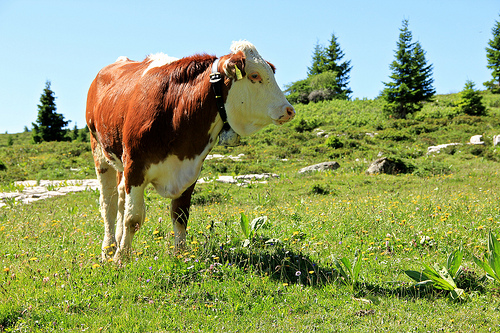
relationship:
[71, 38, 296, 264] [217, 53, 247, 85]
cow has ear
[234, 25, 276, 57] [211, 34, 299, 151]
lump on head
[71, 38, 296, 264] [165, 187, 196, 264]
cow has leg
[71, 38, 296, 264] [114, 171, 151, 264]
cow has leg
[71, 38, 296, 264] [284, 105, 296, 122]
cow has nose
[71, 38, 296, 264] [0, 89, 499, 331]
cow in field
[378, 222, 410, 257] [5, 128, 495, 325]
dandelions on grass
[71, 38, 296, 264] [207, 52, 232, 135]
cow has collar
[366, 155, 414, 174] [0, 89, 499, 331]
stone on field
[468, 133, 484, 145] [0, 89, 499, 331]
stone on field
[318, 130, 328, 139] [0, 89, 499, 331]
stone on field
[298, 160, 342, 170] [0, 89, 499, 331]
stone on field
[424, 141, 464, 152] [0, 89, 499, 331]
stone on field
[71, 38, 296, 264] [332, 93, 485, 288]
cow on pasture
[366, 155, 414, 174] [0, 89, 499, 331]
stone on hill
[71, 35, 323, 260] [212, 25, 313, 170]
cow has face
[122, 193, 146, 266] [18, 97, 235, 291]
markings on legs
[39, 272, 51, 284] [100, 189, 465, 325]
flower in grass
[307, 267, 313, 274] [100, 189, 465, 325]
flower in grass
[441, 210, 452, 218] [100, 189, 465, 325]
flower in grass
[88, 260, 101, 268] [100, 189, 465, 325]
flower in grass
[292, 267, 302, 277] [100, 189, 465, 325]
flower in grass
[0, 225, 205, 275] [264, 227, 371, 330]
flowers in grass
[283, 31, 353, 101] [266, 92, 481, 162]
trees on hill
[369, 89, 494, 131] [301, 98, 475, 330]
shrubs on hill